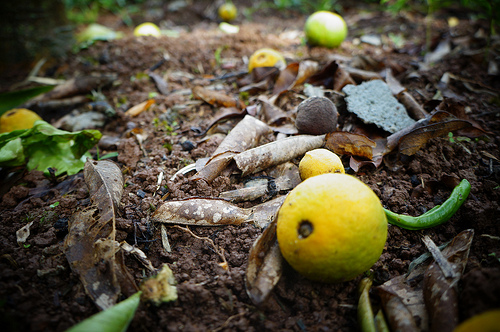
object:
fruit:
[275, 172, 388, 282]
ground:
[0, 179, 271, 332]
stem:
[295, 219, 314, 240]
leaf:
[0, 121, 100, 175]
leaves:
[196, 113, 266, 180]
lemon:
[294, 97, 338, 134]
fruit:
[305, 10, 345, 48]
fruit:
[298, 149, 345, 180]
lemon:
[0, 107, 40, 133]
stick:
[420, 233, 454, 277]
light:
[318, 15, 340, 26]